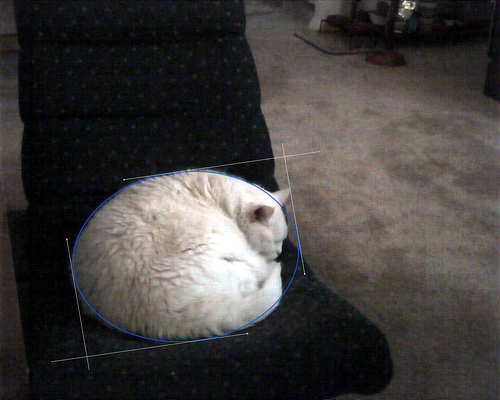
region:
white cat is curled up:
[27, 153, 346, 366]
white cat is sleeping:
[47, 145, 327, 361]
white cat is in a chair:
[15, 93, 409, 392]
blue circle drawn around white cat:
[25, 135, 332, 380]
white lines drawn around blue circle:
[20, 108, 357, 379]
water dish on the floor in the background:
[350, 39, 415, 76]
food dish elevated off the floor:
[304, 4, 393, 74]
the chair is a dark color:
[17, 91, 396, 398]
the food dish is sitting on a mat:
[272, 14, 407, 89]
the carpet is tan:
[276, 79, 496, 359]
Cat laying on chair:
[51, 133, 323, 373]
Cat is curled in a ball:
[72, 148, 368, 331]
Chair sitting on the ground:
[54, 73, 134, 149]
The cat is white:
[62, 155, 323, 346]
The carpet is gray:
[338, 184, 453, 287]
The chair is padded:
[12, 43, 342, 384]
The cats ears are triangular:
[242, 180, 291, 230]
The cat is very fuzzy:
[122, 207, 232, 271]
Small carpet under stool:
[293, 18, 376, 57]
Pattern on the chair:
[86, 62, 164, 128]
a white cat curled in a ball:
[77, 169, 289, 339]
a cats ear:
[250, 202, 279, 224]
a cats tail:
[227, 266, 286, 331]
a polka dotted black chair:
[12, 0, 394, 399]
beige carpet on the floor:
[250, 4, 497, 397]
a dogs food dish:
[362, 51, 404, 62]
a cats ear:
[275, 185, 290, 205]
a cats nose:
[275, 245, 280, 255]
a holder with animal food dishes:
[320, 6, 375, 46]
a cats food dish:
[345, 15, 367, 27]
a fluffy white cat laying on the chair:
[71, 171, 290, 334]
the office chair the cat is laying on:
[9, 5, 400, 398]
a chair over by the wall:
[319, 7, 385, 37]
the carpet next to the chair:
[253, 32, 489, 398]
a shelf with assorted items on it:
[373, 5, 462, 36]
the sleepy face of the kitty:
[264, 225, 292, 260]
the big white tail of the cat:
[223, 269, 286, 330]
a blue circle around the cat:
[76, 163, 315, 348]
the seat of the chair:
[28, 248, 391, 395]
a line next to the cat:
[281, 138, 318, 286]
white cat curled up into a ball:
[49, 157, 306, 349]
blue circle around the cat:
[67, 163, 314, 349]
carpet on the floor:
[0, 13, 497, 398]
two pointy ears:
[237, 176, 303, 232]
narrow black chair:
[5, 2, 397, 399]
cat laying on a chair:
[12, 8, 387, 399]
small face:
[252, 198, 297, 262]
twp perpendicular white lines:
[39, 231, 255, 387]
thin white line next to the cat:
[274, 123, 331, 297]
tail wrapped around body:
[212, 261, 296, 333]